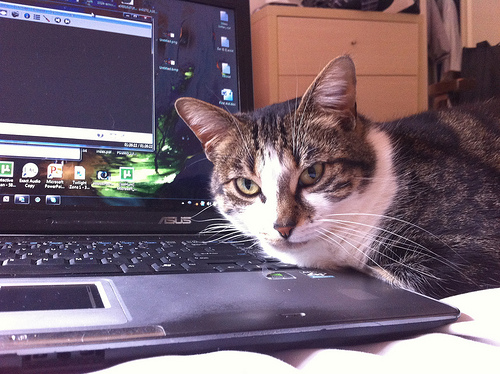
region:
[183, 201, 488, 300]
long white whiskers of grey+white american shorthair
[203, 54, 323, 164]
long white eyebrow whiskers of american shorthair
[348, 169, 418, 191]
stray cheek whisker of shorthair grey+brown+white cat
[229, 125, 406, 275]
the shorthair's white ruff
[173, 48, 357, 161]
bushy white fur in cat's inner ears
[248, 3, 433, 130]
nondescript light wood cabinet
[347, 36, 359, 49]
cabinet's puny drawer-pull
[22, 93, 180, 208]
green+golden colors on monitor's background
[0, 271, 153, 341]
laptop's touchpad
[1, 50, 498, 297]
furry animal inspects laptop, keyboard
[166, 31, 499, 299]
Cat is lying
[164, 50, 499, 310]
Cat is laying facing a computer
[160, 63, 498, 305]
Cat is dark grey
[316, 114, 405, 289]
Cat has white fur in the neck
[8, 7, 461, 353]
Black computer near cat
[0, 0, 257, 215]
Computer screen is open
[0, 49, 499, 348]
Cat is touching the keyboard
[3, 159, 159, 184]
Icons of software in screen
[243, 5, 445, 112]
White cabinet in office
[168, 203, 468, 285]
White whiskers of cat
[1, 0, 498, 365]
the photo is clear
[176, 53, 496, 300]
an animal is in the photo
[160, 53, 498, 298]
the animal is a cat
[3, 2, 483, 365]
the photo was taken indoors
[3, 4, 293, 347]
a laptop is in the photo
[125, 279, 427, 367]
the laptop is black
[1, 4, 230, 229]
the laptop is on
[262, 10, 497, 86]
a furniture is in the photo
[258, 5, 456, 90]
the furniture is brown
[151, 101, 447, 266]
the cat is looking at the camera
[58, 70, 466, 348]
cat on desk leaning over laptop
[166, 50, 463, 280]
cat with brown, black and white fur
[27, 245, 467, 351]
flat metal panel of laptop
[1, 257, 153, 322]
small panel below the keyboard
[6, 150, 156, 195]
icons in a row at bottom of screen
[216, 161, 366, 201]
oval-shaped green eyes with black centers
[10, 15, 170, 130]
blank, dark grey image on screen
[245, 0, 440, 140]
light-colored cabinet behind cat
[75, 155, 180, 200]
green and white swirl on screen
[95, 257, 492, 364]
white blanket underneath the cat and laptop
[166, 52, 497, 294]
a brown and white cat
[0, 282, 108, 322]
a laptop track pad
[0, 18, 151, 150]
a window on a computer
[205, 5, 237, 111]
a column of icons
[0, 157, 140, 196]
a row of icons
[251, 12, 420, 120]
a piece of furniture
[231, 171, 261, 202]
a yellow cat eye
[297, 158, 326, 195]
another yellow cat eye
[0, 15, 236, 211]
a laptop computer screen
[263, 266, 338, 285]
a pair of stickers